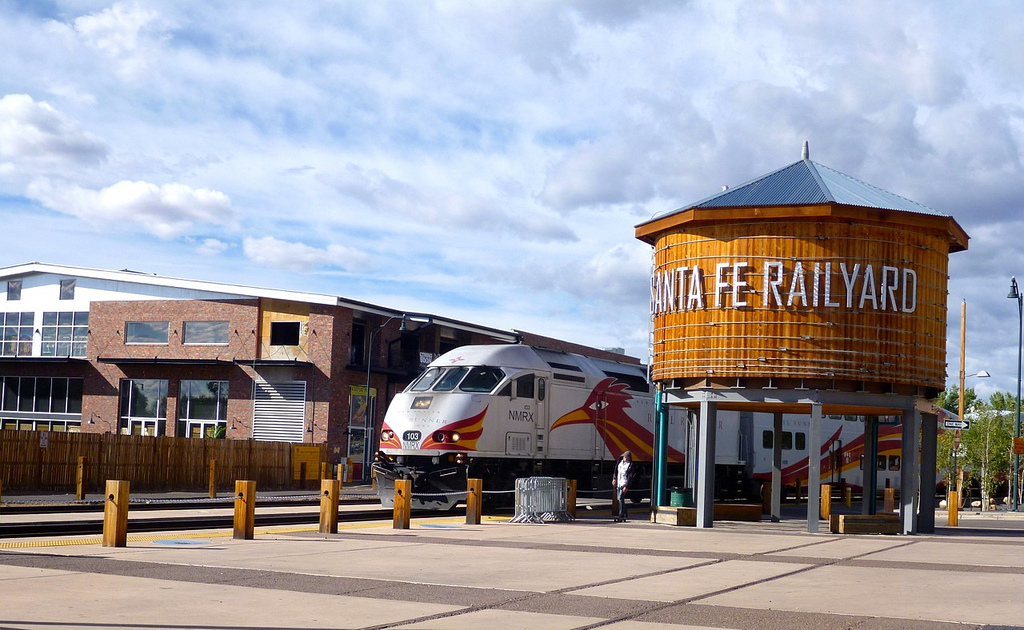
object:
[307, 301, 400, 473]
wall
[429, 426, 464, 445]
headlight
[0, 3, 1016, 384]
clouds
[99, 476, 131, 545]
post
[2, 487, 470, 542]
track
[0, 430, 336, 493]
fence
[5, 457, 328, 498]
railings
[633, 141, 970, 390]
tank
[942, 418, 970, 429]
sign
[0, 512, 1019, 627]
platform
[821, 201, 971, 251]
back corner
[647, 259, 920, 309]
name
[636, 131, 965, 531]
tower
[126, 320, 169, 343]
window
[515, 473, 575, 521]
box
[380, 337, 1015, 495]
train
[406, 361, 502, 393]
window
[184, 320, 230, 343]
window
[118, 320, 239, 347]
window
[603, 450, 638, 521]
man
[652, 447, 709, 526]
can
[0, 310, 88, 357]
window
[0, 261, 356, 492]
building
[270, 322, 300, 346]
window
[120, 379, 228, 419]
window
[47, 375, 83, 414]
window